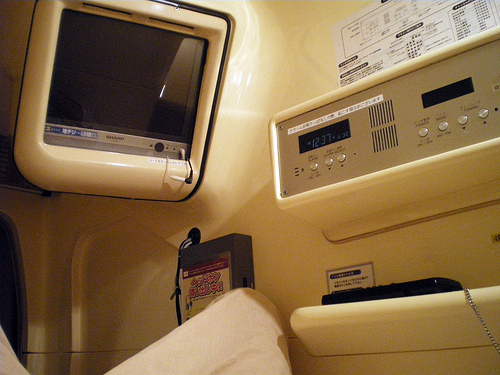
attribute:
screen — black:
[288, 103, 368, 163]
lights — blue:
[309, 127, 336, 147]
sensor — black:
[151, 142, 166, 153]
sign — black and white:
[335, 0, 495, 80]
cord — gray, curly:
[458, 285, 498, 356]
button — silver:
[337, 153, 343, 159]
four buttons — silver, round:
[416, 105, 492, 138]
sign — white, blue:
[325, 260, 375, 292]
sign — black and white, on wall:
[331, 1, 498, 91]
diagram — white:
[336, 2, 498, 60]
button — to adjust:
[175, 145, 186, 163]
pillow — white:
[165, 313, 250, 356]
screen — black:
[42, 7, 209, 160]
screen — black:
[42, 10, 202, 149]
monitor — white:
[10, 0, 240, 195]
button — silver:
[478, 106, 490, 121]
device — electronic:
[259, 28, 499, 233]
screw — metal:
[272, 122, 278, 130]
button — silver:
[408, 125, 444, 144]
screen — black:
[45, 7, 208, 141]